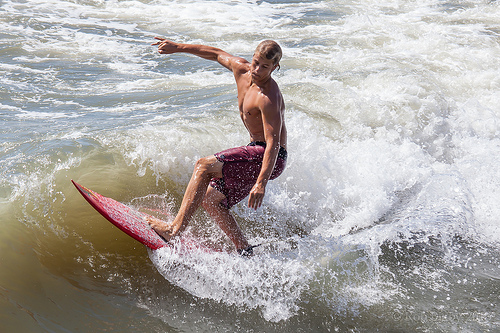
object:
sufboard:
[69, 177, 231, 260]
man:
[150, 35, 287, 257]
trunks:
[187, 142, 287, 210]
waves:
[0, 0, 499, 333]